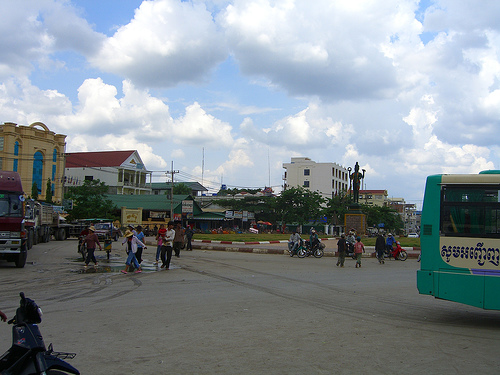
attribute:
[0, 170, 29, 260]
bus — red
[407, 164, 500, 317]
bus — green, white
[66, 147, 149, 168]
roof — red, gray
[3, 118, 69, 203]
building — yellow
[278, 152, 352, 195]
building — white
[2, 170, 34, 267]
truck — dark red, burgundy bus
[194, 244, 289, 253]
curb — red, white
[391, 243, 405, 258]
scooter — red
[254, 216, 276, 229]
umbrella — red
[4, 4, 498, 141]
cloud — white